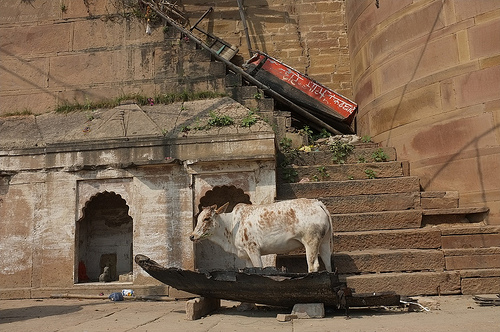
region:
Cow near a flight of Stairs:
[181, 188, 346, 278]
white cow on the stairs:
[186, 191, 351, 276]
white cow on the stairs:
[161, 165, 264, 288]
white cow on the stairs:
[219, 185, 275, 267]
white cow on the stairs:
[183, 200, 283, 318]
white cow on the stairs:
[190, 195, 272, 274]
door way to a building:
[68, 187, 144, 273]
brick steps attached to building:
[313, 154, 479, 286]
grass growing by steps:
[288, 144, 403, 169]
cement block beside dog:
[286, 302, 326, 320]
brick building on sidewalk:
[346, 5, 491, 145]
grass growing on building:
[6, 80, 233, 102]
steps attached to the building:
[168, 27, 347, 121]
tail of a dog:
[321, 204, 348, 244]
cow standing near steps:
[187, 195, 337, 274]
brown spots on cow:
[253, 207, 299, 235]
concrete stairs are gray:
[343, 195, 458, 286]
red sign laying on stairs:
[240, 47, 355, 122]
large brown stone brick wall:
[25, 20, 137, 100]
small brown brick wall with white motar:
[296, 20, 341, 65]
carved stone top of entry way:
[75, 186, 130, 221]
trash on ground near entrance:
[105, 285, 131, 300]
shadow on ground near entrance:
[1, 300, 77, 320]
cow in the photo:
[182, 169, 334, 262]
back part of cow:
[263, 187, 349, 266]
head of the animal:
[170, 193, 232, 251]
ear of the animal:
[203, 189, 238, 226]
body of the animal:
[236, 187, 315, 255]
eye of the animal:
[196, 207, 222, 231]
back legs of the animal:
[286, 227, 348, 282]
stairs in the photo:
[339, 161, 443, 273]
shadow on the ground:
[19, 283, 87, 330]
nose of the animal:
[178, 224, 209, 246]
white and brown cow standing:
[183, 198, 338, 276]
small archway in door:
[60, 189, 139, 304]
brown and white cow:
[188, 202, 328, 269]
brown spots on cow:
[250, 203, 298, 233]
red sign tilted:
[259, 37, 359, 124]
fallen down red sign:
[241, 49, 358, 134]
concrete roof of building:
[8, 97, 250, 142]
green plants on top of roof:
[173, 110, 263, 135]